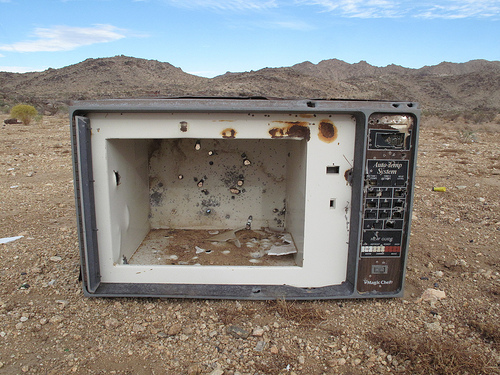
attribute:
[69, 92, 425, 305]
microwave — dumped, missing, doorless, needing, missing door, rusted out, rusted, broken, white, old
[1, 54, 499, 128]
hill — in background, distant, rocky, dirt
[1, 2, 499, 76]
sky — bright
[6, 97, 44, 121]
bush — green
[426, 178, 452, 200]
object — yellow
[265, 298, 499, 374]
vegetation — dead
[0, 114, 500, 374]
dirt — brown, rocky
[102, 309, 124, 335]
rock — small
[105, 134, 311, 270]
interior — white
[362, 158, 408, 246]
keypad — brown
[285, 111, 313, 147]
spot — brown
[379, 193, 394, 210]
button — black